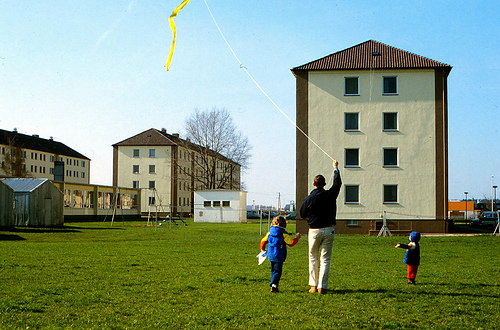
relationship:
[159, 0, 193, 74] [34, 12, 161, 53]
kite in sky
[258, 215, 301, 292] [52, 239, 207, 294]
child in grass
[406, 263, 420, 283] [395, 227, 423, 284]
pants are on child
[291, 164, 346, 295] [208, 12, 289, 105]
man holding string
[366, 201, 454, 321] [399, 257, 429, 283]
boy wearing pants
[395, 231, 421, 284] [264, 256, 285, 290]
boy wearing pants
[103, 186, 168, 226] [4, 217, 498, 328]
swing on grass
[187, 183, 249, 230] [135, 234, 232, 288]
shack on grass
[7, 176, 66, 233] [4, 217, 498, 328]
shed on grass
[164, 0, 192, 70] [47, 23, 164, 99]
kite in sky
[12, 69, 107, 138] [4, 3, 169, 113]
clouds in sky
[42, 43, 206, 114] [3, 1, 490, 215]
clouds in sky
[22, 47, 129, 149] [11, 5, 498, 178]
clouds in sky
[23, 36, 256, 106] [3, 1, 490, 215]
clouds in sky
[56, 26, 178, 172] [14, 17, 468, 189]
clouds in sky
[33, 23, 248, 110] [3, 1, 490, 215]
clouds in sky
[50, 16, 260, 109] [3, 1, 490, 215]
clouds in sky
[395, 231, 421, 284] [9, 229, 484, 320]
boy in grass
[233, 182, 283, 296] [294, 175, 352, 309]
child by man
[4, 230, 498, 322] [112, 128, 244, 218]
area behind building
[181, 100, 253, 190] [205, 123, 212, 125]
tree has branch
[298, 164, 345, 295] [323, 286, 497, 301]
man has shadow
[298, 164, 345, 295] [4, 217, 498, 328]
man on grass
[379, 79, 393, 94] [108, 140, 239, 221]
windows on building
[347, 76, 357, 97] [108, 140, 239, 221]
windows on building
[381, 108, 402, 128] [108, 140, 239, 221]
windows on building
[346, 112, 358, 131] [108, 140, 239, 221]
windows on building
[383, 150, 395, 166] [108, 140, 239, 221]
windows on building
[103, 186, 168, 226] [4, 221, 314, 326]
swing on yard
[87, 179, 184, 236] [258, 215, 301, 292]
swing for child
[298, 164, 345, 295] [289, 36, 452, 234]
man front building